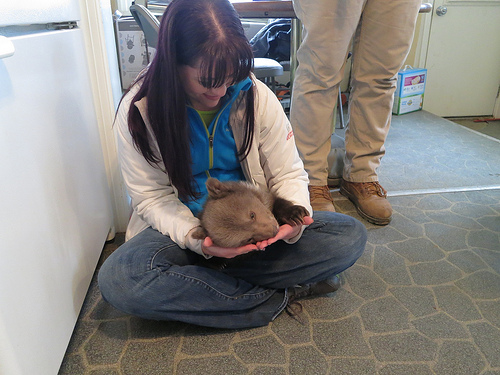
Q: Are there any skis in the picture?
A: No, there are no skis.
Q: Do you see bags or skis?
A: No, there are no skis or bags.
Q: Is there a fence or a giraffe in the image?
A: No, there are no fences or giraffes.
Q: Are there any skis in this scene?
A: No, there are no skis.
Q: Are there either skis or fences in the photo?
A: No, there are no skis or fences.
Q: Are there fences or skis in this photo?
A: No, there are no skis or fences.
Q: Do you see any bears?
A: Yes, there is a bear.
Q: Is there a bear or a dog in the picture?
A: Yes, there is a bear.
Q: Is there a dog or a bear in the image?
A: Yes, there is a bear.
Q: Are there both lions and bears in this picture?
A: No, there is a bear but no lions.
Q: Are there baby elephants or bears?
A: Yes, there is a baby bear.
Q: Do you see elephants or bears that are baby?
A: Yes, the bear is a baby.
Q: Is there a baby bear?
A: Yes, there is a baby bear.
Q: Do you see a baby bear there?
A: Yes, there is a baby bear.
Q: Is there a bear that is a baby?
A: Yes, there is a bear that is a baby.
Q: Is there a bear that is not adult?
A: Yes, there is an baby bear.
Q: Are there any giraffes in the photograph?
A: No, there are no giraffes.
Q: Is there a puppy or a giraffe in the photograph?
A: No, there are no giraffes or puppies.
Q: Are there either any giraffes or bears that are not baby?
A: No, there is a bear but it is a baby.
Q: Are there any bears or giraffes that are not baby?
A: No, there is a bear but it is a baby.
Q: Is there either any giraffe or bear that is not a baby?
A: No, there is a bear but it is a baby.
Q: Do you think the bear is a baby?
A: Yes, the bear is a baby.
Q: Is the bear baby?
A: Yes, the bear is a baby.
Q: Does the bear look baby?
A: Yes, the bear is a baby.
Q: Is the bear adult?
A: No, the bear is a baby.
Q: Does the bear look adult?
A: No, the bear is a baby.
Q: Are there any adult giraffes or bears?
A: No, there is a bear but it is a baby.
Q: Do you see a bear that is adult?
A: No, there is a bear but it is a baby.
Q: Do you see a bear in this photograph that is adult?
A: No, there is a bear but it is a baby.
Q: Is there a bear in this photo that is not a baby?
A: No, there is a bear but it is a baby.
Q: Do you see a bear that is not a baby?
A: No, there is a bear but it is a baby.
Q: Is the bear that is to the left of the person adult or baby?
A: The bear is a baby.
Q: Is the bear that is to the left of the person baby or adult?
A: The bear is a baby.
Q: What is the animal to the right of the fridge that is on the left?
A: The animal is a bear.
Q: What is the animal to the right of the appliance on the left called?
A: The animal is a bear.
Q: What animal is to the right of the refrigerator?
A: The animal is a bear.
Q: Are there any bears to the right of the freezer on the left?
A: Yes, there is a bear to the right of the fridge.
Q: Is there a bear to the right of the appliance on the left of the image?
A: Yes, there is a bear to the right of the fridge.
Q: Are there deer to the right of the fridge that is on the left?
A: No, there is a bear to the right of the freezer.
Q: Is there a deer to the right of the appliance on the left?
A: No, there is a bear to the right of the freezer.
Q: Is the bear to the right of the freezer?
A: Yes, the bear is to the right of the freezer.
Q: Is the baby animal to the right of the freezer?
A: Yes, the bear is to the right of the freezer.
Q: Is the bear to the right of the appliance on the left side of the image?
A: Yes, the bear is to the right of the freezer.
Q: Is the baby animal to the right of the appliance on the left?
A: Yes, the bear is to the right of the freezer.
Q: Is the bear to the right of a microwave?
A: No, the bear is to the right of the freezer.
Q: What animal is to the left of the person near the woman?
A: The animal is a bear.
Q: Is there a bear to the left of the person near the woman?
A: Yes, there is a bear to the left of the person.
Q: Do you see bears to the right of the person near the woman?
A: No, the bear is to the left of the person.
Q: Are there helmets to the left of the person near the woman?
A: No, there is a bear to the left of the person.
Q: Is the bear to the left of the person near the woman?
A: Yes, the bear is to the left of the person.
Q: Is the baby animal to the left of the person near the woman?
A: Yes, the bear is to the left of the person.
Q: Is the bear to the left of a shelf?
A: No, the bear is to the left of the person.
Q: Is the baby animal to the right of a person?
A: No, the bear is to the left of a person.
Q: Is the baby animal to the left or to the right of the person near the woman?
A: The bear is to the left of the person.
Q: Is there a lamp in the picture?
A: No, there are no lamps.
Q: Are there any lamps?
A: No, there are no lamps.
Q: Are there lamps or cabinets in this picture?
A: No, there are no lamps or cabinets.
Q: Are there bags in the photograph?
A: No, there are no bags.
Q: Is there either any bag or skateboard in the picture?
A: No, there are no bags or skateboards.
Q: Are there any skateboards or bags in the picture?
A: No, there are no bags or skateboards.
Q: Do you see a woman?
A: Yes, there is a woman.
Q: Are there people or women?
A: Yes, there is a woman.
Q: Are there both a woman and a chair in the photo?
A: Yes, there are both a woman and a chair.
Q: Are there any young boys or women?
A: Yes, there is a young woman.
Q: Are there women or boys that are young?
A: Yes, the woman is young.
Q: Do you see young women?
A: Yes, there is a young woman.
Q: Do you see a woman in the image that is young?
A: Yes, there is a woman that is young.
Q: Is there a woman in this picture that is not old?
A: Yes, there is an young woman.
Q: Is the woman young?
A: Yes, the woman is young.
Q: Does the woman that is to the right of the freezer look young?
A: Yes, the woman is young.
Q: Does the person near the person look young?
A: Yes, the woman is young.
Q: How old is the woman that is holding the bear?
A: The woman is young.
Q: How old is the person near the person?
A: The woman is young.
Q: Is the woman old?
A: No, the woman is young.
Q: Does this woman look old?
A: No, the woman is young.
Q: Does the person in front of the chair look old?
A: No, the woman is young.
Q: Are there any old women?
A: No, there is a woman but she is young.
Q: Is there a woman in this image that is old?
A: No, there is a woman but she is young.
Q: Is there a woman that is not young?
A: No, there is a woman but she is young.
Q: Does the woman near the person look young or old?
A: The woman is young.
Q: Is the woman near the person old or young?
A: The woman is young.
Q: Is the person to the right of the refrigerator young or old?
A: The woman is young.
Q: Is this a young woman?
A: Yes, this is a young woman.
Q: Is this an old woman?
A: No, this is a young woman.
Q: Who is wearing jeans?
A: The woman is wearing jeans.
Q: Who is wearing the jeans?
A: The woman is wearing jeans.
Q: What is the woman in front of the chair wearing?
A: The woman is wearing jeans.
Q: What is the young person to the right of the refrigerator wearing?
A: The woman is wearing jeans.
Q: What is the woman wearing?
A: The woman is wearing jeans.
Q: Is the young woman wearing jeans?
A: Yes, the woman is wearing jeans.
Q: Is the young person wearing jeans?
A: Yes, the woman is wearing jeans.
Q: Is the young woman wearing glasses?
A: No, the woman is wearing jeans.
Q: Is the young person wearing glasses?
A: No, the woman is wearing jeans.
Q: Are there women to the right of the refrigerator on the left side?
A: Yes, there is a woman to the right of the freezer.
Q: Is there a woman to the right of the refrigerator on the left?
A: Yes, there is a woman to the right of the freezer.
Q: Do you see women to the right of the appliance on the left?
A: Yes, there is a woman to the right of the freezer.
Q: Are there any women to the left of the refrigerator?
A: No, the woman is to the right of the refrigerator.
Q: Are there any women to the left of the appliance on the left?
A: No, the woman is to the right of the refrigerator.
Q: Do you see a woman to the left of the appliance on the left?
A: No, the woman is to the right of the refrigerator.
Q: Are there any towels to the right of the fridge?
A: No, there is a woman to the right of the fridge.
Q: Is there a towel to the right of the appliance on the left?
A: No, there is a woman to the right of the fridge.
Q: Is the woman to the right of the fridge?
A: Yes, the woman is to the right of the fridge.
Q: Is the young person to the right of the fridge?
A: Yes, the woman is to the right of the fridge.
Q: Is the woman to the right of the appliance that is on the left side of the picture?
A: Yes, the woman is to the right of the fridge.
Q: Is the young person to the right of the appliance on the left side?
A: Yes, the woman is to the right of the fridge.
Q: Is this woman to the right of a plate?
A: No, the woman is to the right of the fridge.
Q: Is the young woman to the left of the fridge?
A: No, the woman is to the right of the fridge.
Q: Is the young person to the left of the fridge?
A: No, the woman is to the right of the fridge.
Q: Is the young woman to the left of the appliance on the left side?
A: No, the woman is to the right of the fridge.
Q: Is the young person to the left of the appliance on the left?
A: No, the woman is to the right of the fridge.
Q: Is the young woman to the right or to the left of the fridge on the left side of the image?
A: The woman is to the right of the refrigerator.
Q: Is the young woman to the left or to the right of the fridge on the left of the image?
A: The woman is to the right of the refrigerator.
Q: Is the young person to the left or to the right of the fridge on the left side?
A: The woman is to the right of the refrigerator.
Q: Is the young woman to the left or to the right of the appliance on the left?
A: The woman is to the right of the refrigerator.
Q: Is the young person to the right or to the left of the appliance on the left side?
A: The woman is to the right of the refrigerator.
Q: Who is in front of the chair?
A: The woman is in front of the chair.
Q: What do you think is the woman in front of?
A: The woman is in front of the chair.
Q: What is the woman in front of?
A: The woman is in front of the chair.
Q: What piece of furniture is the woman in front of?
A: The woman is in front of the chair.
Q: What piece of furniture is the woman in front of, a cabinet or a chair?
A: The woman is in front of a chair.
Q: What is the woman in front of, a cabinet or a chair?
A: The woman is in front of a chair.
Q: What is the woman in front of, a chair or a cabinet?
A: The woman is in front of a chair.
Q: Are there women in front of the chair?
A: Yes, there is a woman in front of the chair.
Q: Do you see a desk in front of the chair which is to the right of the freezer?
A: No, there is a woman in front of the chair.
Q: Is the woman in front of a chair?
A: Yes, the woman is in front of a chair.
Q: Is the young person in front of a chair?
A: Yes, the woman is in front of a chair.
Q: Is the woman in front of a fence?
A: No, the woman is in front of a chair.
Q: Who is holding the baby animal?
A: The woman is holding the bear.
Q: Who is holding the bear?
A: The woman is holding the bear.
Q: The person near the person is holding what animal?
A: The woman is holding the bear.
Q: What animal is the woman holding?
A: The woman is holding the bear.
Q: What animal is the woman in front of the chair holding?
A: The woman is holding the bear.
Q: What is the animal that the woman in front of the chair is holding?
A: The animal is a bear.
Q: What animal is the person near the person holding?
A: The woman is holding the bear.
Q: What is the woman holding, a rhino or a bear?
A: The woman is holding a bear.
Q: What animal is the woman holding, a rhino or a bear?
A: The woman is holding a bear.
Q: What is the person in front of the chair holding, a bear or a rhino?
A: The woman is holding a bear.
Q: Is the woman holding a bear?
A: Yes, the woman is holding a bear.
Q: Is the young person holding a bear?
A: Yes, the woman is holding a bear.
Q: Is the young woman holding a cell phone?
A: No, the woman is holding a bear.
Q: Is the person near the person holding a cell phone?
A: No, the woman is holding a bear.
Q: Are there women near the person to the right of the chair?
A: Yes, there is a woman near the person.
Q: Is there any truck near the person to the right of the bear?
A: No, there is a woman near the person.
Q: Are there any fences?
A: No, there are no fences.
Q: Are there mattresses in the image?
A: No, there are no mattresses.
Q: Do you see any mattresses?
A: No, there are no mattresses.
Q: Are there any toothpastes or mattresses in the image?
A: No, there are no mattresses or toothpastes.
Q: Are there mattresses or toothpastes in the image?
A: No, there are no mattresses or toothpastes.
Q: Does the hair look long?
A: Yes, the hair is long.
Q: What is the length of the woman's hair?
A: The hair is long.